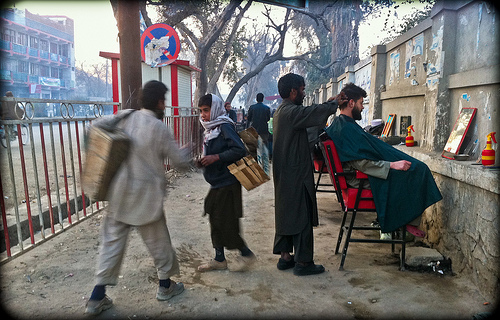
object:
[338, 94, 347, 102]
clippers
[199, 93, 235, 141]
headwrap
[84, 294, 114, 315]
foot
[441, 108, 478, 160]
mirror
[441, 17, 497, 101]
stone wall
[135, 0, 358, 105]
branches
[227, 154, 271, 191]
purse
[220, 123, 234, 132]
shoulder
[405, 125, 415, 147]
spray bottle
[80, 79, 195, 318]
man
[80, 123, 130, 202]
basket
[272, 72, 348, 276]
barber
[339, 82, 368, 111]
hair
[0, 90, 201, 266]
fence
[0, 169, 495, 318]
ground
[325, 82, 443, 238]
man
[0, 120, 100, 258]
red shirt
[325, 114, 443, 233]
cape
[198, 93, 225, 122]
head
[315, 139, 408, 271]
barber's chair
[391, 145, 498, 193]
ledge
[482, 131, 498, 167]
bottle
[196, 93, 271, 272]
person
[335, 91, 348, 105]
hand